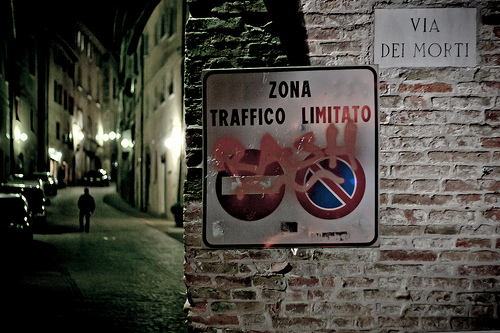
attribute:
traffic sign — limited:
[199, 61, 383, 253]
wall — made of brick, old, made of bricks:
[177, 1, 499, 332]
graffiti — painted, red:
[213, 118, 360, 200]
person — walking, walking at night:
[78, 184, 99, 235]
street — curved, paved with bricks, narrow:
[1, 181, 190, 332]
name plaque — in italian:
[372, 4, 479, 72]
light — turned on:
[19, 130, 30, 144]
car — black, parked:
[78, 166, 112, 188]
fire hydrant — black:
[169, 201, 185, 230]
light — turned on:
[68, 124, 85, 148]